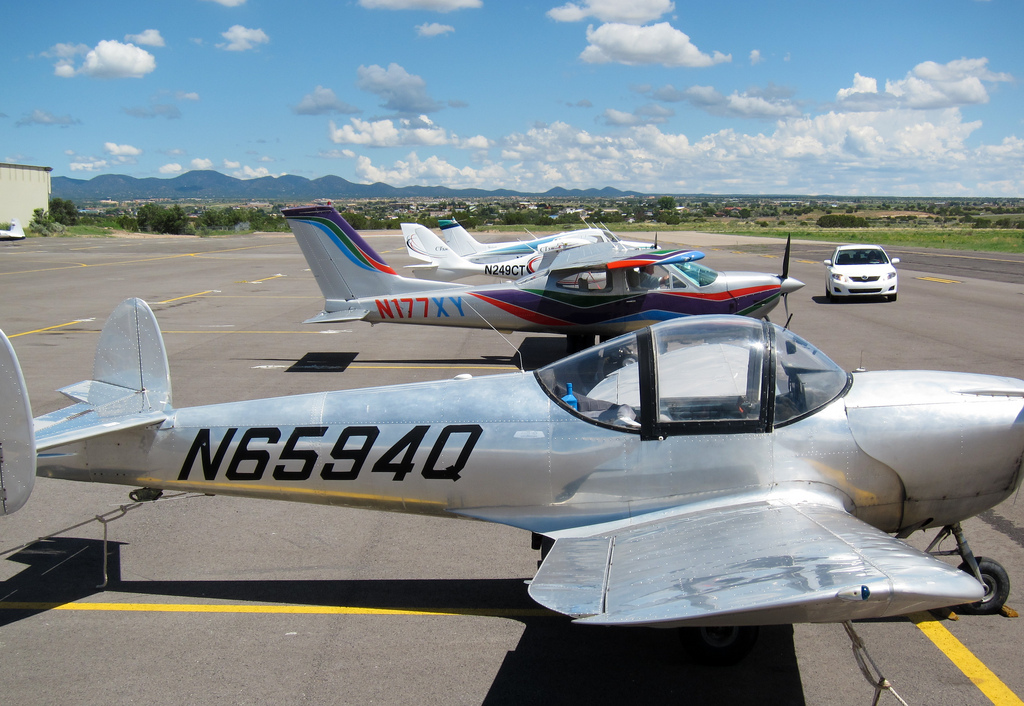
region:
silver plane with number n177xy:
[250, 193, 802, 340]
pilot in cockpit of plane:
[612, 244, 712, 306]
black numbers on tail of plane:
[147, 400, 524, 518]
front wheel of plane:
[899, 485, 1016, 623]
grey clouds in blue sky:
[283, 52, 476, 128]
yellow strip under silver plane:
[27, 298, 496, 652]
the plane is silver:
[10, 301, 1020, 657]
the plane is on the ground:
[8, 303, 1020, 657]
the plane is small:
[6, 303, 1022, 659]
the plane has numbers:
[171, 416, 465, 484]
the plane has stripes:
[284, 200, 784, 347]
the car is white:
[822, 237, 895, 294]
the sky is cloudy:
[5, 7, 1015, 203]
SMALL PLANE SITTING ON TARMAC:
[282, 202, 792, 332]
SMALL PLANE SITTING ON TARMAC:
[393, 221, 654, 278]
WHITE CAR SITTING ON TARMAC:
[816, 234, 921, 293]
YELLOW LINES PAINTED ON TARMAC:
[912, 601, 1017, 696]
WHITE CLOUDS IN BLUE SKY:
[560, 35, 795, 137]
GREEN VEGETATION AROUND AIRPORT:
[61, 177, 913, 253]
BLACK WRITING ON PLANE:
[189, 420, 491, 491]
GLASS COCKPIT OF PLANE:
[562, 322, 825, 434]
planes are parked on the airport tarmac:
[5, 205, 1021, 703]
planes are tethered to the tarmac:
[0, 200, 1023, 691]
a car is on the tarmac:
[803, 233, 920, 332]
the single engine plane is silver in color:
[8, 297, 1023, 652]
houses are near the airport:
[84, 193, 816, 239]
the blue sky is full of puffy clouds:
[18, 0, 1022, 171]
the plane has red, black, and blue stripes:
[278, 196, 804, 343]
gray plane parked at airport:
[30, 283, 1018, 666]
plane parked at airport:
[290, 192, 777, 317]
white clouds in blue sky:
[84, 37, 167, 73]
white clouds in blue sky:
[811, 42, 889, 118]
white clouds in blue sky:
[597, 34, 667, 73]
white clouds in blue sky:
[395, 43, 469, 91]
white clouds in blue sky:
[527, 107, 614, 161]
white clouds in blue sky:
[160, 50, 249, 98]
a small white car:
[824, 247, 902, 302]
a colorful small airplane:
[275, 209, 797, 331]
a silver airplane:
[41, 309, 1022, 643]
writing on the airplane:
[178, 419, 477, 484]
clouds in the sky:
[305, 103, 999, 168]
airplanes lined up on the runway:
[47, 189, 1019, 635]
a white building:
[8, 164, 47, 238]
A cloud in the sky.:
[653, 73, 712, 102]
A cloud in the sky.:
[708, 90, 779, 126]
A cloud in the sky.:
[830, 70, 903, 91]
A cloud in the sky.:
[363, 61, 441, 100]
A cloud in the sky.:
[414, 20, 462, 41]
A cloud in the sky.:
[218, 23, 263, 49]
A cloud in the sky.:
[73, 36, 154, 81]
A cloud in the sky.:
[136, 29, 172, 46]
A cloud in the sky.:
[44, 39, 105, 55]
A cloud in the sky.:
[568, 20, 747, 72]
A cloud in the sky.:
[419, 19, 446, 38]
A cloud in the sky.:
[353, 57, 418, 84]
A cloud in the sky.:
[369, 87, 453, 123]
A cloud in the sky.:
[294, 92, 361, 119]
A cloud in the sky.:
[205, 21, 298, 60]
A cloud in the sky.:
[123, 27, 166, 53]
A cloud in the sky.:
[49, 52, 79, 75]